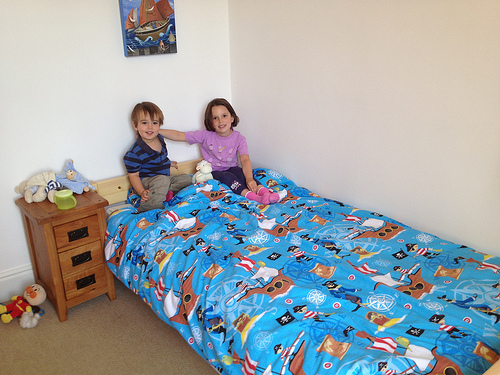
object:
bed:
[79, 159, 499, 374]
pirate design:
[427, 313, 475, 338]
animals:
[55, 158, 99, 194]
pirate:
[124, 244, 150, 273]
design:
[123, 246, 151, 273]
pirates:
[301, 230, 341, 253]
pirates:
[237, 280, 252, 292]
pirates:
[392, 267, 409, 274]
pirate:
[288, 244, 313, 263]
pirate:
[293, 303, 330, 324]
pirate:
[193, 235, 220, 257]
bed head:
[85, 156, 203, 209]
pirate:
[323, 275, 368, 315]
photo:
[116, 0, 179, 57]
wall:
[1, 0, 231, 279]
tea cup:
[54, 187, 76, 211]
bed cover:
[105, 168, 498, 374]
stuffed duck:
[0, 282, 52, 329]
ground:
[0, 280, 220, 374]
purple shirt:
[184, 127, 252, 172]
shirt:
[120, 133, 170, 179]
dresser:
[15, 186, 117, 322]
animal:
[0, 281, 55, 323]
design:
[342, 257, 437, 303]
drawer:
[52, 212, 103, 253]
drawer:
[57, 238, 109, 278]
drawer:
[60, 261, 114, 299]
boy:
[123, 101, 191, 212]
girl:
[159, 97, 283, 208]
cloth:
[105, 166, 499, 374]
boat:
[232, 244, 295, 302]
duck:
[3, 282, 43, 331]